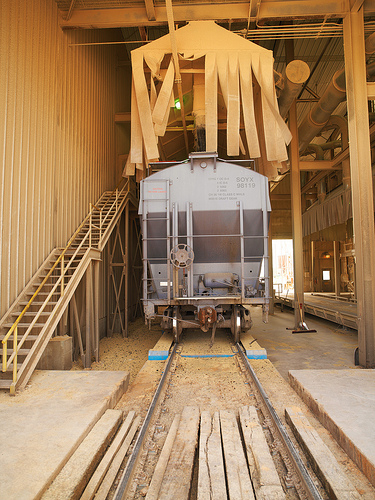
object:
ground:
[0, 364, 129, 499]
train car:
[136, 157, 273, 333]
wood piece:
[143, 413, 180, 500]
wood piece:
[159, 405, 198, 499]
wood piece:
[219, 411, 256, 499]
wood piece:
[198, 409, 227, 499]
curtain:
[131, 50, 159, 158]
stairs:
[42, 266, 77, 274]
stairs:
[23, 291, 55, 304]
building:
[2, 1, 375, 499]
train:
[140, 153, 268, 345]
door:
[272, 238, 297, 296]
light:
[173, 98, 180, 110]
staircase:
[0, 183, 129, 396]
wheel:
[226, 304, 243, 342]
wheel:
[166, 304, 184, 341]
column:
[289, 102, 304, 325]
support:
[343, 8, 375, 368]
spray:
[209, 321, 218, 343]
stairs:
[0, 360, 21, 378]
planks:
[237, 406, 288, 500]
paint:
[148, 347, 268, 363]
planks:
[283, 406, 361, 498]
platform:
[0, 372, 129, 499]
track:
[112, 336, 323, 498]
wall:
[0, 1, 118, 317]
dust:
[27, 376, 74, 398]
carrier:
[134, 146, 273, 338]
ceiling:
[73, 11, 352, 144]